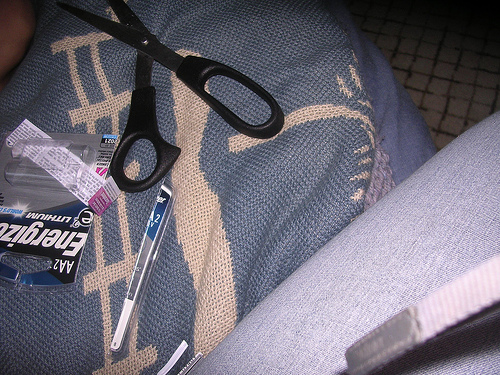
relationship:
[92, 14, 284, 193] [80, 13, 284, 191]
pair of scissors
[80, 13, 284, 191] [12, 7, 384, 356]
scissors on top of blanket